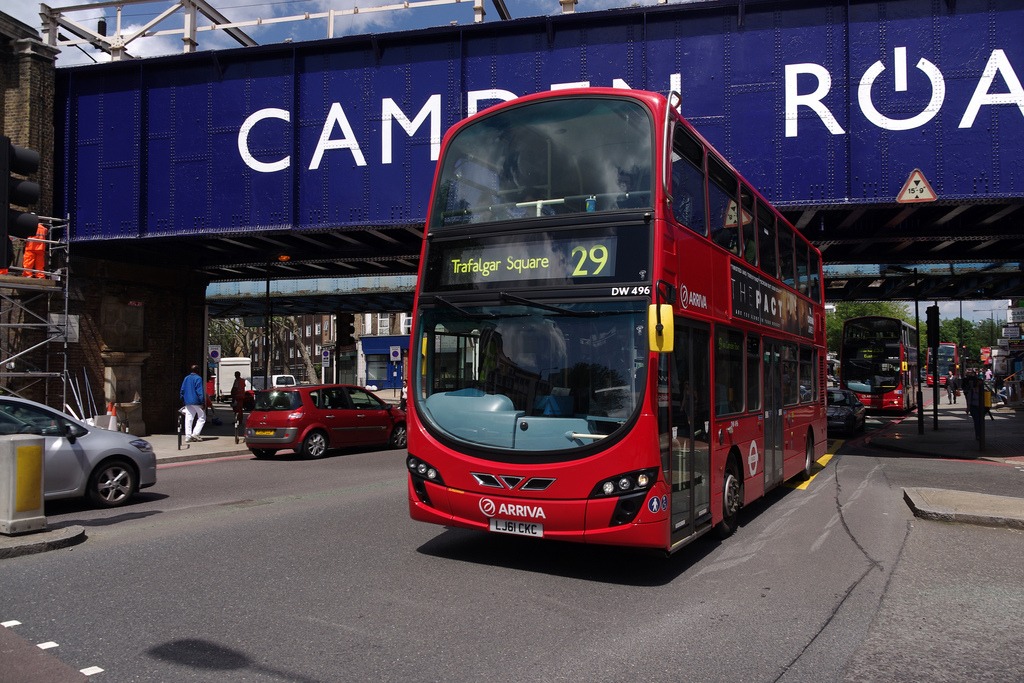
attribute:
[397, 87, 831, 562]
doubledecker bus — double decker, real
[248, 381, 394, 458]
car — red, small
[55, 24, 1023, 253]
overpass — large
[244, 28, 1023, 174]
letters — blue, white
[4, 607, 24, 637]
square — white, small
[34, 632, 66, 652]
square — white, small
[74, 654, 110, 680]
square — white, small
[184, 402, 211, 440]
pants — white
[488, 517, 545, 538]
license plate — white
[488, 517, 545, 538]
letters — black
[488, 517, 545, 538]
numbers — black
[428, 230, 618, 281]
sign — black, informational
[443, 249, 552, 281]
letters — yellow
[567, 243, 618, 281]
numbers — yellow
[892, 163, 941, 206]
sign — red, white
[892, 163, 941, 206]
letters — black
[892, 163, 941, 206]
symbols — black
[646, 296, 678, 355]
side mirror — large, yellow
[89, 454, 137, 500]
tire — black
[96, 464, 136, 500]
rim — silver